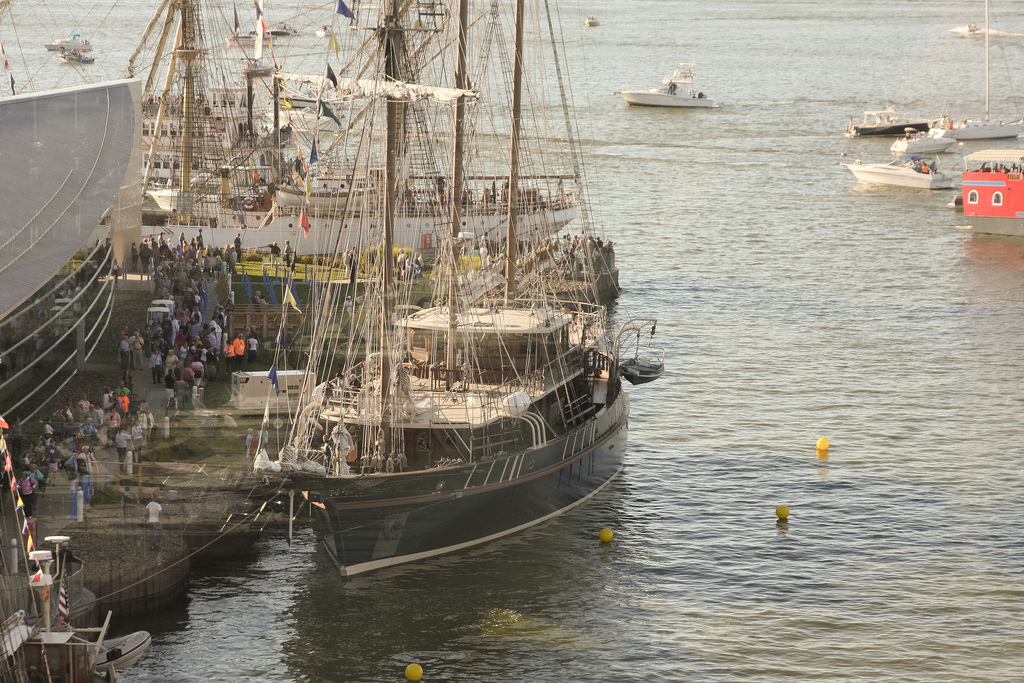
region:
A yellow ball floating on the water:
[768, 500, 800, 530]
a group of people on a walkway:
[60, 296, 239, 503]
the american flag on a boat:
[43, 552, 85, 629]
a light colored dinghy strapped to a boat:
[44, 616, 166, 671]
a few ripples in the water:
[875, 503, 996, 634]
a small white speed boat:
[612, 54, 724, 124]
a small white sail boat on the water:
[931, 12, 1018, 158]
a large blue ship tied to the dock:
[261, 0, 676, 607]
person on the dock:
[117, 399, 131, 420]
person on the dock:
[197, 339, 220, 379]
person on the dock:
[20, 454, 53, 518]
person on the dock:
[162, 278, 207, 308]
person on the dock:
[118, 344, 186, 386]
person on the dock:
[213, 259, 220, 269]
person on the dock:
[159, 319, 183, 354]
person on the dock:
[241, 361, 255, 372]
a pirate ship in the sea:
[309, 2, 636, 581]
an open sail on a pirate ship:
[0, 75, 137, 317]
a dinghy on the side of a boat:
[616, 352, 664, 382]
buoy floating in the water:
[814, 435, 831, 451]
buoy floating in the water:
[774, 504, 788, 520]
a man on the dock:
[141, 494, 165, 527]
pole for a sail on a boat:
[451, 1, 467, 372]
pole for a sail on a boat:
[508, 4, 528, 311]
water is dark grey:
[696, 351, 909, 429]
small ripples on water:
[746, 246, 895, 418]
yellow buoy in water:
[766, 407, 862, 459]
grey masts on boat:
[125, 0, 558, 304]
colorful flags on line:
[234, 23, 356, 464]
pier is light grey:
[58, 316, 254, 579]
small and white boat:
[813, 135, 950, 199]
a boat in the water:
[315, 360, 625, 646]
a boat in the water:
[410, 224, 535, 300]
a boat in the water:
[425, 80, 511, 218]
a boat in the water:
[160, 59, 244, 165]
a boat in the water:
[931, 155, 1018, 216]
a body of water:
[672, 341, 968, 680]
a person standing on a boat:
[220, 244, 256, 277]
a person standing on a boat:
[157, 246, 184, 272]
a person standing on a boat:
[197, 222, 237, 267]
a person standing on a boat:
[548, 250, 593, 282]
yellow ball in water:
[398, 651, 424, 680]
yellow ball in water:
[590, 522, 633, 549]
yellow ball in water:
[770, 496, 805, 522]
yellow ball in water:
[799, 426, 844, 461]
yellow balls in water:
[758, 426, 836, 526]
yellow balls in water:
[585, 423, 848, 556]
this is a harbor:
[127, 45, 954, 625]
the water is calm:
[691, 184, 963, 586]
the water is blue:
[674, 153, 963, 572]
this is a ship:
[146, 114, 772, 517]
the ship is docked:
[408, 194, 750, 643]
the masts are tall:
[311, 48, 572, 415]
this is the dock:
[115, 329, 347, 674]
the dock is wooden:
[87, 339, 343, 548]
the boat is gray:
[236, 311, 642, 543]